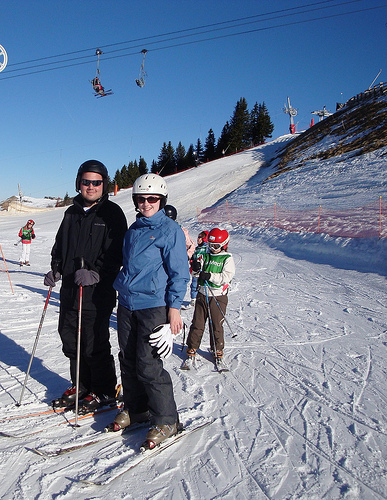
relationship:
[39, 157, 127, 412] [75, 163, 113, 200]
man wearing a helmet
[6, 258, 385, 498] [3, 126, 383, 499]
tracks in snow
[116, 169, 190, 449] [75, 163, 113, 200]
woman wearing a helmet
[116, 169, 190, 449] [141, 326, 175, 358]
woman holding glove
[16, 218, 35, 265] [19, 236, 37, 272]
person wearing pants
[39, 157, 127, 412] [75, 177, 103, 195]
man wearing sunglasses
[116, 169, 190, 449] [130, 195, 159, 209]
woman wearing sunglasses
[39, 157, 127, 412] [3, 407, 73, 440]
man standing on skis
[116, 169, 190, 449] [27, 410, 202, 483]
woman standing on skis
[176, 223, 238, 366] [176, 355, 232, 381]
child standing on skis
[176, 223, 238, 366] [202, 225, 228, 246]
child wearing helmet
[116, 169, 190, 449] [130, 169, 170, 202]
woman wearing a helmet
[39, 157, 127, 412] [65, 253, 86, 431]
man holding ski pole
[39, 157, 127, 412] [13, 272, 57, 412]
man holding ski pole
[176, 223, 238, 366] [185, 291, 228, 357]
child wearing pants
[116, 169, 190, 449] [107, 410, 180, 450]
woman wearing boots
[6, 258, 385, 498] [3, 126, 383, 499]
tracks are on snow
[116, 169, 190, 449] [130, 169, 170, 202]
woman wearing helmet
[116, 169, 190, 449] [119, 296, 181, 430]
woman wearing pants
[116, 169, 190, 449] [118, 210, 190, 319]
woman wearing a jacket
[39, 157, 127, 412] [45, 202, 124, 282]
man wearing a jacket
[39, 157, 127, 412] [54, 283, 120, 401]
man wearing pants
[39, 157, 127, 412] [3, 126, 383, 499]
man standing on snow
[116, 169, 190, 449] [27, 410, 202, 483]
woman wearing skis